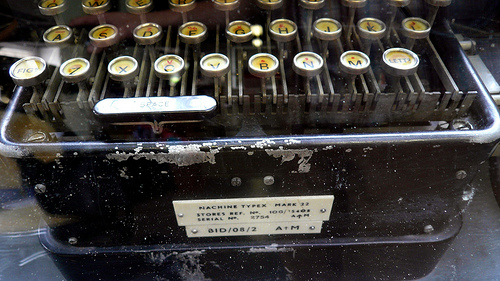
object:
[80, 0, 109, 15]
w key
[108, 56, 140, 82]
key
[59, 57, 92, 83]
key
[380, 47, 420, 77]
key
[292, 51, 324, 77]
key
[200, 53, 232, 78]
key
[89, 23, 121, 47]
key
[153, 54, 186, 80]
key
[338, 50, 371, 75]
key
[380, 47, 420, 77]
tin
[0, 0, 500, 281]
typewriter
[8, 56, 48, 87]
key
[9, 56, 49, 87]
tin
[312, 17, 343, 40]
j key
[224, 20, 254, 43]
tin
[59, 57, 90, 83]
button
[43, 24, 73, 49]
key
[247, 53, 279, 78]
b key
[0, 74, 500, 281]
tin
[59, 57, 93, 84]
tin